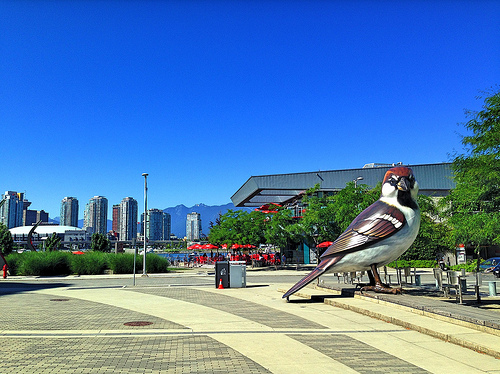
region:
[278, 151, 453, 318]
a large bird statue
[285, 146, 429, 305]
a statue of a brown and white bird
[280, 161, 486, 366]
a statue on pavers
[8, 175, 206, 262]
tall buildings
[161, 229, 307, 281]
tables with red umbrellas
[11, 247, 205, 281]
green bushes along roadside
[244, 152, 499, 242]
a building with a grey roof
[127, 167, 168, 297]
a streetlight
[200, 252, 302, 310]
two trash recepticals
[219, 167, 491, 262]
trees beside a building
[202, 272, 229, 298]
white and orange traffic cone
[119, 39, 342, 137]
clear bright blue sky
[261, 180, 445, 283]
white and brown large bird statue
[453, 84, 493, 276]
green large tree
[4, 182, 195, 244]
large city sky line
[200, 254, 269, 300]
white and black metal trash cans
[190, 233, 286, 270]
row of red dining umbrellas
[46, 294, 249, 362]
stone and cement park pathway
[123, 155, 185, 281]
silver tall street light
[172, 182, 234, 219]
distant view of mountain scenery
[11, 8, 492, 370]
Outdoor scenario, daytime, showing summer-like features.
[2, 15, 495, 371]
Metropolitan close-up with city skyline.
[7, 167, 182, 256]
Distant city skyline with high tower.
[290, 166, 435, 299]
Giant artwork of red-topped bird.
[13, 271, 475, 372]
Walkway showing cream stripes on cobbled, grey surface.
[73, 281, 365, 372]
Line arcs, suggesting gentle sloping of terrain.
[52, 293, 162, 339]
Brown grate tops.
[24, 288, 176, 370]
Shadows on stone.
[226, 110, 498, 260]
Building roof and greenery.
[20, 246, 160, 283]
Dark, green shrubbery.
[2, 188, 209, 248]
tall buildings in the distance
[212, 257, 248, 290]
garbage and recycling cans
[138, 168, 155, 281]
a light pole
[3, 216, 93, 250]
a stadium in the distance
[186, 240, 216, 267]
red umbrella's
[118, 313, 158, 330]
a manhole with cover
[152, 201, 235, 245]
a mountain in the distance with a building in the front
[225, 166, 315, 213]
overhanging roof of a building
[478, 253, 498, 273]
a parked car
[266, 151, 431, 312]
A large statue of a bird.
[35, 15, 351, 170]
The skies are clear.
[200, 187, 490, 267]
Trees surround the building.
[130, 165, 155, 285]
A streetlight.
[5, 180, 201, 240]
High-rise buildings in the background.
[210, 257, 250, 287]
Garbage bins.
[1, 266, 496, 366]
A plaza.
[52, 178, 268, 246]
A mountain range in the distance.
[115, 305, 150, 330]
A manhole in the ground.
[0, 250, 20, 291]
A red fire hydrant.